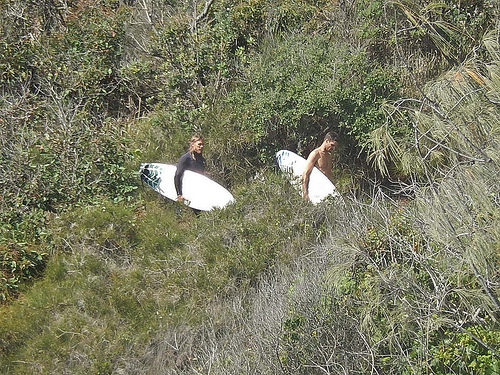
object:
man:
[174, 134, 206, 202]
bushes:
[0, 233, 51, 305]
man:
[302, 131, 339, 202]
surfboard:
[139, 163, 236, 212]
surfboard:
[277, 149, 347, 208]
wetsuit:
[174, 151, 207, 218]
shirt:
[174, 151, 208, 195]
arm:
[174, 156, 189, 195]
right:
[369, 0, 500, 375]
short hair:
[324, 131, 340, 145]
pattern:
[140, 164, 165, 193]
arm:
[302, 150, 319, 198]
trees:
[0, 0, 68, 109]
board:
[274, 149, 346, 206]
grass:
[106, 285, 145, 316]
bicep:
[305, 162, 314, 173]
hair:
[187, 133, 204, 161]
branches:
[413, 122, 482, 160]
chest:
[317, 157, 331, 169]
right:
[174, 156, 189, 203]